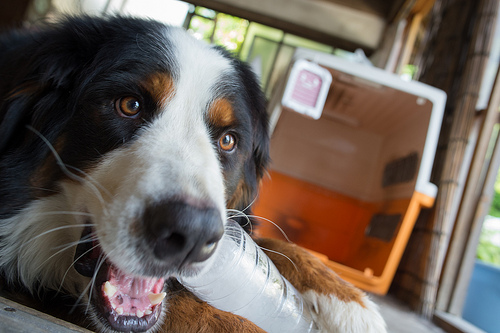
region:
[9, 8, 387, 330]
this is a dog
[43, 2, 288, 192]
black ears on dog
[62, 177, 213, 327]
dog has mouth open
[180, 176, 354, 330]
dog holding a cylinder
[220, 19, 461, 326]
this is a pet crate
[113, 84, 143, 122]
The dogs right eye is brown.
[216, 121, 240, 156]
The dogs left eye is brown.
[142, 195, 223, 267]
The dogs nose is black.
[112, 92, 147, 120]
The dogs right eye is round.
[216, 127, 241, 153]
The dogs left eye is round.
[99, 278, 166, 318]
The dogs teeth are sharp.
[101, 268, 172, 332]
The dogs tongue is pink in color.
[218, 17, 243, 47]
The leaves in the background are green in color.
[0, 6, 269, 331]
The dogs face is brown, black and white.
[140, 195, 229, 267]
nose on cute hairy dog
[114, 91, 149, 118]
eye on cute hairy dog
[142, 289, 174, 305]
tooth on cute hairy dog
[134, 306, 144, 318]
tooth on cute hairy dog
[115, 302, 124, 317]
tooth on cute hairy dog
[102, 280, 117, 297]
tooth on cute hairy dog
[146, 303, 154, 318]
tooth on cute hairy dog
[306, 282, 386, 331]
paw on cute hairy dog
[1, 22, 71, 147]
ear on cute hairy dog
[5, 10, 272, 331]
a white brown and black dog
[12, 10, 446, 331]
a dog restign by its kennel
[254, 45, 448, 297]
an open small dog cage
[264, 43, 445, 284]
dog kennel without a door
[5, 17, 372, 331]
a puppy plays with a toy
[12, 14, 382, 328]
an animal sitting on the floor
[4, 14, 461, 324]
a brown eyed mixed color dog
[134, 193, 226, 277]
Nose of the dog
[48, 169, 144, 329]
The dog's mouth is open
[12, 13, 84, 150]
Ear of a dog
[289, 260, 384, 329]
Paw of the dog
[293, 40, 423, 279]
Kennel in the background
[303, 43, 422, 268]
White and orange kennel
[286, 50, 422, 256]
White and orange kennel in the background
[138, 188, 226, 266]
Black nose of the dog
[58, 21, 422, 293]
this is a dog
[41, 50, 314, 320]
the dog is smiling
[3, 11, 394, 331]
Dog chewing on a plastic bottle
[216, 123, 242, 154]
Left eye of a dog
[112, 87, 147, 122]
Right eye of a dog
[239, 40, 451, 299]
Pet carrier for an animal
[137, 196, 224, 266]
Nose of a dog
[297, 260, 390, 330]
Left paw of a dog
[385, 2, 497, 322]
Open curtain of a window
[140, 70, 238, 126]
Two spots on the face of a dog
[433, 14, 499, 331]
Window with an outdoor view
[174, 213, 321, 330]
Plastic bottle containing a liquid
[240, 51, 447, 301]
the dog cage is orange and white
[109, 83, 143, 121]
the dog's eyes are brown